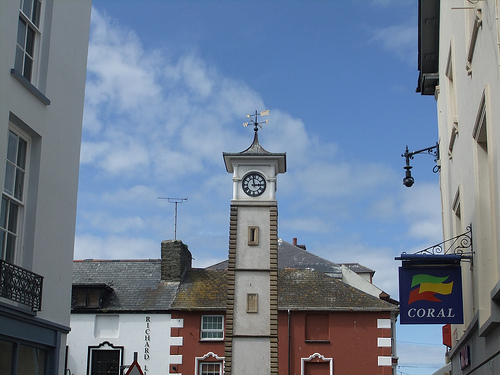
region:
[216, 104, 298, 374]
a clock on a tower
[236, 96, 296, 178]
a weather vane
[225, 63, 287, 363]
a weather vane on a building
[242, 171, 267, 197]
a clock face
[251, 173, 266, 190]
hands of a clock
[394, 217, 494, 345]
a sign that says coral on a building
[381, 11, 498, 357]
a sign attached to a building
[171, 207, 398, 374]
a red brick building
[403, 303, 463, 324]
the words coral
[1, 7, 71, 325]
two windows on a white building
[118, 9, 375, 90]
The sky is the color blue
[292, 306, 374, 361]
The building is the color red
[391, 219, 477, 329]
The sign on the wall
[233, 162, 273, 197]
The clock on the building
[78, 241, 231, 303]
The roof is the color gray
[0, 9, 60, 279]
The window on the side of the building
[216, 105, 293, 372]
The tall building is the color white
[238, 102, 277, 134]
The compass on top of the building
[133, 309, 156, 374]
The name on the building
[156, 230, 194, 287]
The chimney to the building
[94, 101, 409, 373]
a building with a clock tower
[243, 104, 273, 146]
a weather vane on top of a building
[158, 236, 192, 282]
a chimney on top of a building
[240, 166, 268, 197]
the face of a clock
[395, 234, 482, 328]
a sign haning on a building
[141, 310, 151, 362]
the word Richard on a building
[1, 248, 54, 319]
a smal balcony on a building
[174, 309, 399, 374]
a brown building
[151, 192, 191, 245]
an antenna on top of a chimney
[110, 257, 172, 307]
the roof of a building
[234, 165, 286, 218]
clock in tower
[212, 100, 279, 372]
clock tower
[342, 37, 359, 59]
white clouds in blue skywhite clouds in blue sky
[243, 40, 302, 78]
white clouds in blue sky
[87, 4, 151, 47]
white clouds in blue sky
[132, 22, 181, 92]
white clouds in blue sky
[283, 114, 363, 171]
white clouds in blue sky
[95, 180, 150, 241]
white clouds in blue sky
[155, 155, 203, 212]
white clouds in blue sky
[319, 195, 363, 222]
white clouds in blue sky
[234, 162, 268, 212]
black and white clock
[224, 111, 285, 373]
white clock tower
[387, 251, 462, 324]
colorful sign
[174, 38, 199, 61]
white clouds in blue sky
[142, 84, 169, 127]
white clouds in blue sky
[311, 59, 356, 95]
white clouds in blue sky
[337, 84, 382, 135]
white clouds in blue sky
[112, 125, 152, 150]
white clouds in blue sky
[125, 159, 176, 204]
white clouds in blue sky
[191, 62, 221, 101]
white clouds in blue sky